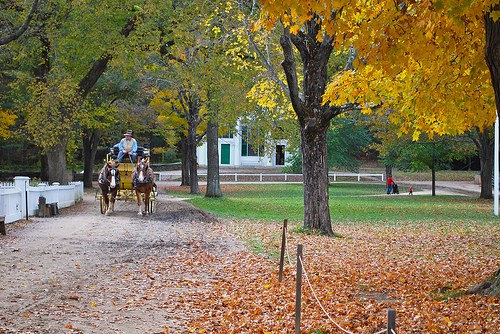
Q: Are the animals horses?
A: Yes, all the animals are horses.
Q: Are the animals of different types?
A: No, all the animals are horses.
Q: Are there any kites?
A: No, there are no kites.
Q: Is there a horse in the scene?
A: Yes, there is a horse.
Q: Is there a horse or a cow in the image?
A: Yes, there is a horse.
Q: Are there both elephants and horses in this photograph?
A: No, there is a horse but no elephants.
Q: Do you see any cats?
A: No, there are no cats.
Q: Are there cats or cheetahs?
A: No, there are no cats or cheetahs.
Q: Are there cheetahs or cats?
A: No, there are no cats or cheetahs.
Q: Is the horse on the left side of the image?
A: Yes, the horse is on the left of the image.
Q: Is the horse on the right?
A: No, the horse is on the left of the image.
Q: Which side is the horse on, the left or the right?
A: The horse is on the left of the image.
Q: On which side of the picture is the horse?
A: The horse is on the left of the image.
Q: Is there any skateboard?
A: No, there are no skateboards.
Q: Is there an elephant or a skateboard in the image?
A: No, there are no skateboards or elephants.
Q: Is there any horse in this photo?
A: Yes, there is a horse.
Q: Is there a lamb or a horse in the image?
A: Yes, there is a horse.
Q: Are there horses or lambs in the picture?
A: Yes, there is a horse.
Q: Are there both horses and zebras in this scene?
A: No, there is a horse but no zebras.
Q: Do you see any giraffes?
A: No, there are no giraffes.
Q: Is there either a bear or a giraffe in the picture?
A: No, there are no giraffes or bears.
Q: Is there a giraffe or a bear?
A: No, there are no giraffes or bears.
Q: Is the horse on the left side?
A: Yes, the horse is on the left of the image.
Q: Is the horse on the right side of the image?
A: No, the horse is on the left of the image.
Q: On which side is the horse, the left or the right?
A: The horse is on the left of the image.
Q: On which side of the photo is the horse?
A: The horse is on the left of the image.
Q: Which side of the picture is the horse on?
A: The horse is on the left of the image.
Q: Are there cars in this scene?
A: No, there are no cars.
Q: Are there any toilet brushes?
A: No, there are no toilet brushes.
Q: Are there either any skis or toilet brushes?
A: No, there are no toilet brushes or skis.